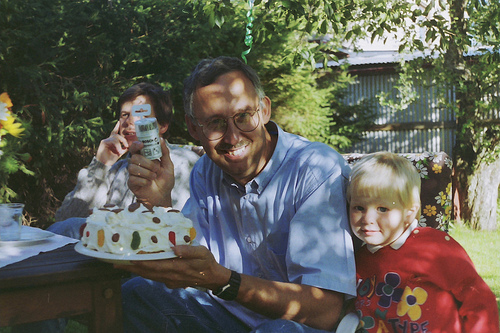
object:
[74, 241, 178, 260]
plate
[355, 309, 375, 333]
flowers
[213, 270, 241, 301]
watch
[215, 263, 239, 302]
wrist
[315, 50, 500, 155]
steel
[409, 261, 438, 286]
part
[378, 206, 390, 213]
eye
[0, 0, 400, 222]
forest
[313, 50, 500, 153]
shed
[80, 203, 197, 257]
cake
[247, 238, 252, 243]
button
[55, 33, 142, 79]
leaves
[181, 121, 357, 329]
shirt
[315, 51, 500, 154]
building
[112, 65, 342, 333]
man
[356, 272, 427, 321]
flowers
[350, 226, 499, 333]
red shirt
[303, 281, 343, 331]
elbow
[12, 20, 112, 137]
bushes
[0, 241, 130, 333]
table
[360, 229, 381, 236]
mouth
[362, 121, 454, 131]
board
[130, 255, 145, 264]
part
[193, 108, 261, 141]
eyeglasses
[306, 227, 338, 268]
part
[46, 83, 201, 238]
people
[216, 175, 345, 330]
arm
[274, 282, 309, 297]
part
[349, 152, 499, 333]
baby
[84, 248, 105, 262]
part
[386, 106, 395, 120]
part